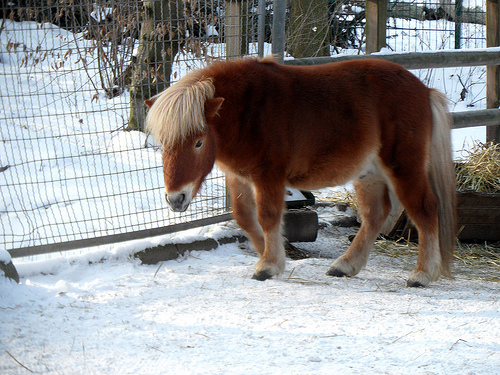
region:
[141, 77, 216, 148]
hair on horse head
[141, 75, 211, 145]
the hair is blonde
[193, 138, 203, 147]
eye of a horse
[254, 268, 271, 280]
the hoof is black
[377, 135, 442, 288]
a leg of a horse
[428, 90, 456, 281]
the tail is blonde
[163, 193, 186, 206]
the nose is black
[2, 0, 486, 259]
a metal fence blocking the horse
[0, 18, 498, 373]
Snow covering the ground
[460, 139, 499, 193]
a pile of hay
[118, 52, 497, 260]
this is a pony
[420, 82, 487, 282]
blonde tail of pony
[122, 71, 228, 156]
blonde mane of pony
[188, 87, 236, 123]
brown ear of pony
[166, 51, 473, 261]
brown body of pony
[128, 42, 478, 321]
pony standing on snow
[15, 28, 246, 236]
wire fence next to pony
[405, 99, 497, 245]
hay on ground behind pony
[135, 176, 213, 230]
white mouth of pony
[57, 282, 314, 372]
hay debris on snow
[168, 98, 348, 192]
this is a pony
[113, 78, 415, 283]
the pony is brown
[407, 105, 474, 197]
this is a long tail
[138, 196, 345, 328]
this is a leg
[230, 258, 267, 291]
this is a hoof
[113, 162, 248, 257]
this is a nose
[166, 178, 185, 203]
the nose is black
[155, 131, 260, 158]
this is an eye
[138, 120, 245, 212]
the eye is black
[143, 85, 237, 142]
this is an ear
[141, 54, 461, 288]
Dwarf horse inside a fence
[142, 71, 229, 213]
Small horse's head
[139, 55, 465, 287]
Beige and brown small horse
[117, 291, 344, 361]
White snow on the ground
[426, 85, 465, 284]
Small horse's long tail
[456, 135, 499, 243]
Hay inside a wood box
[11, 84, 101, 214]
Wire metal cage enclosure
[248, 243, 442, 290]
Small horse four legs standing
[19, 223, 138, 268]
Wire cage partition above with snow underneath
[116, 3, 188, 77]
Tree trunk outside a wire fence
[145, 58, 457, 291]
a brown miniature pony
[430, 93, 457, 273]
the pony's white tail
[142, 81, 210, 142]
white mop of hair on top of head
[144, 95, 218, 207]
pony's head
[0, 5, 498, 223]
metal fence behind the pony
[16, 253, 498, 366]
snowy ground under the pony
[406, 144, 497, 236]
feed trough with hay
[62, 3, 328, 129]
trees in the snow outside the fence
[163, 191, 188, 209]
the pony's nose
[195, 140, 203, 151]
the pony's left eye